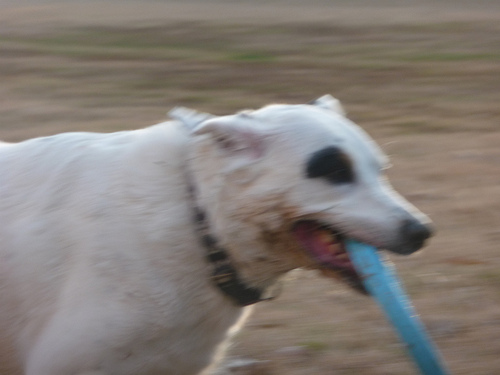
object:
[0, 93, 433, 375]
dog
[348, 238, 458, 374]
frisbee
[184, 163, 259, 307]
collar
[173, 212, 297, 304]
neck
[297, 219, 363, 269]
teeth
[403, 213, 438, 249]
nose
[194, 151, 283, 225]
right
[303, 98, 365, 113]
left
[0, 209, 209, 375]
only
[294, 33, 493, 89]
ground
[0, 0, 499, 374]
background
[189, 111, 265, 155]
ear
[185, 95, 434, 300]
head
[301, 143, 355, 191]
eye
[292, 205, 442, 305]
mouth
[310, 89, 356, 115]
ear